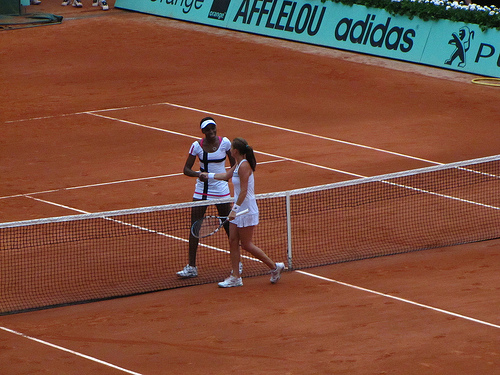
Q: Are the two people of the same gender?
A: Yes, all the people are female.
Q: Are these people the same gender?
A: Yes, all the people are female.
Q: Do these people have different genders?
A: No, all the people are female.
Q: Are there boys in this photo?
A: No, there are no boys.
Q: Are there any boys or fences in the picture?
A: No, there are no boys or fences.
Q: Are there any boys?
A: No, there are no boys.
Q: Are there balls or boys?
A: No, there are no boys or balls.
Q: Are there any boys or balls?
A: No, there are no boys or balls.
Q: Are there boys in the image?
A: No, there are no boys.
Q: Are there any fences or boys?
A: No, there are no boys or fences.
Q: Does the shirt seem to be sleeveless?
A: Yes, the shirt is sleeveless.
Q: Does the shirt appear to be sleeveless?
A: Yes, the shirt is sleeveless.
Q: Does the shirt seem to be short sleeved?
A: No, the shirt is sleeveless.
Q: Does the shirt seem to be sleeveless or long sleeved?
A: The shirt is sleeveless.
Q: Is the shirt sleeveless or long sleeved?
A: The shirt is sleeveless.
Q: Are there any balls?
A: No, there are no balls.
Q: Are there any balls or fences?
A: No, there are no balls or fences.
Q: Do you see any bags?
A: No, there are no bags.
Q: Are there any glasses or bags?
A: No, there are no bags or glasses.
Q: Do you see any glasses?
A: No, there are no glasses.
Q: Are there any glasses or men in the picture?
A: No, there are no glasses or men.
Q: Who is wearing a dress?
A: The lady is wearing a dress.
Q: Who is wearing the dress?
A: The lady is wearing a dress.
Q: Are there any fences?
A: No, there are no fences.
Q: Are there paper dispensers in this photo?
A: No, there are no paper dispensers.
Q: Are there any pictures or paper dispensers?
A: No, there are no paper dispensers or pictures.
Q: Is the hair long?
A: Yes, the hair is long.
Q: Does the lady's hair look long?
A: Yes, the hair is long.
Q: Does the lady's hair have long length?
A: Yes, the hair is long.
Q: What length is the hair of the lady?
A: The hair is long.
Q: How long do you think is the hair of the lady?
A: The hair is long.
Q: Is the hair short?
A: No, the hair is long.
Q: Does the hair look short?
A: No, the hair is long.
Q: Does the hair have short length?
A: No, the hair is long.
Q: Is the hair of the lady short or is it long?
A: The hair is long.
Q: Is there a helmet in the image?
A: No, there are no helmets.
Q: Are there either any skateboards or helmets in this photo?
A: No, there are no helmets or skateboards.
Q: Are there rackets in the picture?
A: Yes, there is a racket.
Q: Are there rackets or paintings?
A: Yes, there is a racket.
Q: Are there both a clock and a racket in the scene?
A: No, there is a racket but no clocks.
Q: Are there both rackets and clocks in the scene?
A: No, there is a racket but no clocks.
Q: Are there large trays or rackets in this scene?
A: Yes, there is a large racket.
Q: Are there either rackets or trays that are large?
A: Yes, the racket is large.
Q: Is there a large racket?
A: Yes, there is a large racket.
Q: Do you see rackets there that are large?
A: Yes, there is a racket that is large.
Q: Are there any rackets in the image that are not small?
A: Yes, there is a large racket.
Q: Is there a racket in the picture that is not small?
A: Yes, there is a large racket.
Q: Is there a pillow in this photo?
A: No, there are no pillows.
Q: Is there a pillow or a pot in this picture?
A: No, there are no pillows or pots.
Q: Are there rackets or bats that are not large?
A: No, there is a racket but it is large.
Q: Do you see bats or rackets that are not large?
A: No, there is a racket but it is large.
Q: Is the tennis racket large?
A: Yes, the tennis racket is large.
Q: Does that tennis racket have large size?
A: Yes, the tennis racket is large.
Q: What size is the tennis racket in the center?
A: The tennis racket is large.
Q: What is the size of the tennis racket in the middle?
A: The tennis racket is large.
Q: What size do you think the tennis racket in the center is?
A: The tennis racket is large.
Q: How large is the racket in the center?
A: The racket is large.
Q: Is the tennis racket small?
A: No, the tennis racket is large.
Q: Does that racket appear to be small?
A: No, the racket is large.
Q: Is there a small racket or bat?
A: No, there is a racket but it is large.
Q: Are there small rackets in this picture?
A: No, there is a racket but it is large.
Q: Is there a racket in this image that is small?
A: No, there is a racket but it is large.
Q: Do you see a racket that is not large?
A: No, there is a racket but it is large.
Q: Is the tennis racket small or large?
A: The tennis racket is large.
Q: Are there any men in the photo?
A: No, there are no men.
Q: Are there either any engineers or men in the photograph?
A: No, there are no men or engineers.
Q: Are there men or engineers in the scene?
A: No, there are no men or engineers.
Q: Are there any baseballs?
A: No, there are no baseballs.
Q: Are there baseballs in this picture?
A: No, there are no baseballs.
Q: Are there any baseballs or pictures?
A: No, there are no baseballs or pictures.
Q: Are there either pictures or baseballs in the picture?
A: No, there are no baseballs or pictures.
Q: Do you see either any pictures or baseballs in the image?
A: No, there are no baseballs or pictures.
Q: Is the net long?
A: Yes, the net is long.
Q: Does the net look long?
A: Yes, the net is long.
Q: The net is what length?
A: The net is long.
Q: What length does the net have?
A: The net has long length.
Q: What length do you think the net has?
A: The net has long length.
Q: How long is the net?
A: The net is long.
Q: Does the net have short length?
A: No, the net is long.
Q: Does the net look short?
A: No, the net is long.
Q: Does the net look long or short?
A: The net is long.